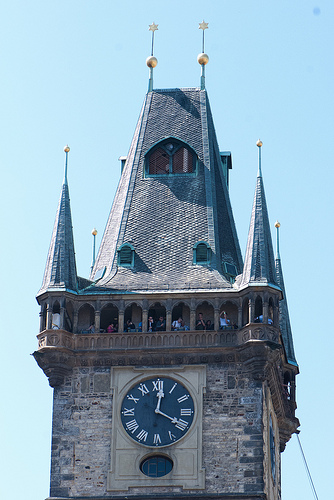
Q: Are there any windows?
A: Yes, there is a window.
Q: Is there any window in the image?
A: Yes, there is a window.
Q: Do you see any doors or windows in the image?
A: Yes, there is a window.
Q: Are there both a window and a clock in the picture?
A: Yes, there are both a window and a clock.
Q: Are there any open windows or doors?
A: Yes, there is an open window.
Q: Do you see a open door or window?
A: Yes, there is an open window.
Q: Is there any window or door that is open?
A: Yes, the window is open.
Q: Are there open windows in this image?
A: Yes, there is an open window.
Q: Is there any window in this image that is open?
A: Yes, there is a window that is open.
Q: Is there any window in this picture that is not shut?
A: Yes, there is a open window.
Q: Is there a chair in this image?
A: No, there are no chairs.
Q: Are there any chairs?
A: No, there are no chairs.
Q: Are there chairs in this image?
A: No, there are no chairs.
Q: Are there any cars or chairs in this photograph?
A: No, there are no chairs or cars.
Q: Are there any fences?
A: No, there are no fences.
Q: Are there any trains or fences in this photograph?
A: No, there are no fences or trains.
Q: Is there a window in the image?
A: Yes, there is a window.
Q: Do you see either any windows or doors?
A: Yes, there is a window.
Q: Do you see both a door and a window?
A: No, there is a window but no doors.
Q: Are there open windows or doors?
A: Yes, there is an open window.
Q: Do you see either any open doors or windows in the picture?
A: Yes, there is an open window.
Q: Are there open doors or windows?
A: Yes, there is an open window.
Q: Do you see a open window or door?
A: Yes, there is an open window.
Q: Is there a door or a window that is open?
A: Yes, the window is open.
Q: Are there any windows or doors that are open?
A: Yes, the window is open.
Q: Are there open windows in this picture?
A: Yes, there is an open window.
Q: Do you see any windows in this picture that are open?
A: Yes, there is an open window.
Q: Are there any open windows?
A: Yes, there is an open window.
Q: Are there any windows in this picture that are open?
A: Yes, there is a window that is open.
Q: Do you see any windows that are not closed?
A: Yes, there is a open window.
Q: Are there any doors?
A: No, there are no doors.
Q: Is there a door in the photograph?
A: No, there are no doors.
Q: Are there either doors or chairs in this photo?
A: No, there are no doors or chairs.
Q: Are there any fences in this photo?
A: No, there are no fences.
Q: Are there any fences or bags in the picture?
A: No, there are no fences or bags.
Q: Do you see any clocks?
A: Yes, there is a clock.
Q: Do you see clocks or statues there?
A: Yes, there is a clock.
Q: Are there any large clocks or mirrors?
A: Yes, there is a large clock.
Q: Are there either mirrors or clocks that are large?
A: Yes, the clock is large.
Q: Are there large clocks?
A: Yes, there is a large clock.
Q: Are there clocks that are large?
A: Yes, there is a clock that is large.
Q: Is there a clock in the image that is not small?
A: Yes, there is a large clock.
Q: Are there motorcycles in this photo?
A: No, there are no motorcycles.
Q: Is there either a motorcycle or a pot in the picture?
A: No, there are no motorcycles or pots.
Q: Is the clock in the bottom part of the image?
A: Yes, the clock is in the bottom of the image.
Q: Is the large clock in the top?
A: No, the clock is in the bottom of the image.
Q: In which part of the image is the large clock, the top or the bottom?
A: The clock is in the bottom of the image.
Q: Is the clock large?
A: Yes, the clock is large.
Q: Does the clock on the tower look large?
A: Yes, the clock is large.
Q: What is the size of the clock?
A: The clock is large.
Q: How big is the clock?
A: The clock is large.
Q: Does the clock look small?
A: No, the clock is large.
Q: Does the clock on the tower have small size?
A: No, the clock is large.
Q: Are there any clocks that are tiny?
A: No, there is a clock but it is large.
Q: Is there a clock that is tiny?
A: No, there is a clock but it is large.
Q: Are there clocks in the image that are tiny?
A: No, there is a clock but it is large.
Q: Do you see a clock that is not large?
A: No, there is a clock but it is large.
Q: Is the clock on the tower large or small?
A: The clock is large.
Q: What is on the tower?
A: The clock is on the tower.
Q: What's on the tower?
A: The clock is on the tower.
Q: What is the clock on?
A: The clock is on the tower.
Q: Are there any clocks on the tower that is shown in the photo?
A: Yes, there is a clock on the tower.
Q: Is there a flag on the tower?
A: No, there is a clock on the tower.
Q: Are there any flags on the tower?
A: No, there is a clock on the tower.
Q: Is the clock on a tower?
A: Yes, the clock is on a tower.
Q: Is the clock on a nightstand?
A: No, the clock is on a tower.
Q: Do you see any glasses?
A: No, there are no glasses.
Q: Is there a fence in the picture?
A: No, there are no fences.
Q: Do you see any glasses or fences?
A: No, there are no fences or glasses.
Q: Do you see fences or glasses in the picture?
A: No, there are no fences or glasses.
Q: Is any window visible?
A: Yes, there is a window.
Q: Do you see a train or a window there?
A: Yes, there is a window.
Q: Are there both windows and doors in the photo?
A: No, there is a window but no doors.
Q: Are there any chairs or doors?
A: No, there are no chairs or doors.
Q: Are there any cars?
A: No, there are no cars.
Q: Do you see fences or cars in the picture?
A: No, there are no cars or fences.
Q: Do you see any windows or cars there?
A: Yes, there is a window.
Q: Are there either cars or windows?
A: Yes, there is a window.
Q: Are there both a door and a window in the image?
A: No, there is a window but no doors.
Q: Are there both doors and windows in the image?
A: No, there is a window but no doors.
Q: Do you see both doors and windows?
A: No, there is a window but no doors.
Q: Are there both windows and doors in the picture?
A: No, there is a window but no doors.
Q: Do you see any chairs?
A: No, there are no chairs.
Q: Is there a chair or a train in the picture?
A: No, there are no chairs or trains.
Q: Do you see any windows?
A: Yes, there is a window.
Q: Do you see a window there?
A: Yes, there is a window.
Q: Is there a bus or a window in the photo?
A: Yes, there is a window.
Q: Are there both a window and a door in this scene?
A: No, there is a window but no doors.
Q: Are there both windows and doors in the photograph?
A: No, there is a window but no doors.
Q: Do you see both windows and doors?
A: No, there is a window but no doors.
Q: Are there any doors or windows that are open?
A: Yes, the window is open.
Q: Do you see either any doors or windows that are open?
A: Yes, the window is open.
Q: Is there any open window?
A: Yes, there is an open window.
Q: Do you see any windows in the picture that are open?
A: Yes, there is a window that is open.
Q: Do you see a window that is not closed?
A: Yes, there is a open window.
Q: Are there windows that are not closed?
A: Yes, there is a open window.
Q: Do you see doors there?
A: No, there are no doors.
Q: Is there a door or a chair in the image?
A: No, there are no doors or chairs.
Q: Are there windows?
A: Yes, there is a window.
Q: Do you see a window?
A: Yes, there is a window.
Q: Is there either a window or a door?
A: Yes, there is a window.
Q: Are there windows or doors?
A: Yes, there is a window.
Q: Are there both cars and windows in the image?
A: No, there is a window but no cars.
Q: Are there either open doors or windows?
A: Yes, there is an open window.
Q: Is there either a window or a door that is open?
A: Yes, the window is open.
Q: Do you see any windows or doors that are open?
A: Yes, the window is open.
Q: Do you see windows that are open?
A: Yes, there is an open window.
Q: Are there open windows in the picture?
A: Yes, there is an open window.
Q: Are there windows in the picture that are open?
A: Yes, there is a window that is open.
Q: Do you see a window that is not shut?
A: Yes, there is a open window.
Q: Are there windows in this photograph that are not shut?
A: Yes, there is a open window.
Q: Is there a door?
A: No, there are no doors.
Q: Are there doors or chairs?
A: No, there are no doors or chairs.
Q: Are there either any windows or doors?
A: Yes, there is a window.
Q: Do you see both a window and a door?
A: No, there is a window but no doors.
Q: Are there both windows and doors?
A: No, there is a window but no doors.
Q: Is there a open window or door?
A: Yes, there is an open window.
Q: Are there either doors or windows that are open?
A: Yes, the window is open.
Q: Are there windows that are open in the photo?
A: Yes, there is an open window.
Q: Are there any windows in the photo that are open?
A: Yes, there is a window that is open.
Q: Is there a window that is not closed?
A: Yes, there is a open window.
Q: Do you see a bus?
A: No, there are no buses.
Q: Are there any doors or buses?
A: No, there are no buses or doors.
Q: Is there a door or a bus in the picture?
A: No, there are no buses or doors.